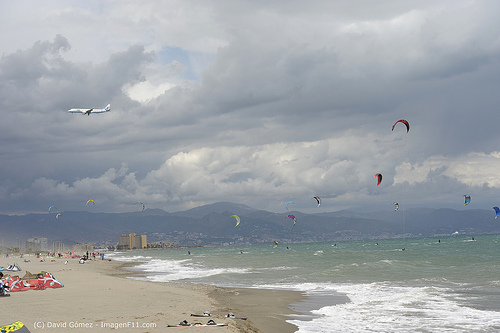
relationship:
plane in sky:
[66, 98, 109, 123] [166, 70, 233, 111]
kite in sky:
[383, 112, 424, 138] [166, 70, 233, 111]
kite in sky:
[370, 161, 403, 205] [166, 70, 233, 111]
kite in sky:
[447, 186, 474, 211] [166, 70, 233, 111]